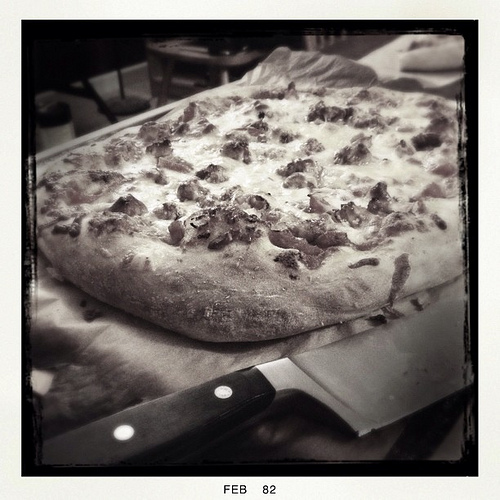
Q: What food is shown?
A: Pizza.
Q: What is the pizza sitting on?
A: A table.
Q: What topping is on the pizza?
A: Hamburger or sausage.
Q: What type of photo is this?
A: Black and white.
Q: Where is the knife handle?
A: Top left of knife.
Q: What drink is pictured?
A: There isn't a drink.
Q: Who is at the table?
A: There are no people.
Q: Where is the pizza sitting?
A: On top of aluminum foil.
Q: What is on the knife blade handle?
A: Two silver dots.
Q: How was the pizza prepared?
A: Baked in oven.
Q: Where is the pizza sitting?
A: On top of cloth napkin.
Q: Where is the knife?
A: Next to the pizza.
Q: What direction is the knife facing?
A: To the right.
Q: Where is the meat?
A: On the pizza.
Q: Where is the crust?
A: On edges of pizza.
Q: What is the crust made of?
A: Bread.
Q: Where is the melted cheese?
A: On the pizza.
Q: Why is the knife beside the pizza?
A: To cut the pizza.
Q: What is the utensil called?
A: A knife.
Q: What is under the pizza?
A: A table.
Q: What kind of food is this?
A: Pizza.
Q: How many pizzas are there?
A: 1.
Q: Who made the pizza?
A: Cook.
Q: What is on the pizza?
A: Meat.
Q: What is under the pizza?
A: Cutting board.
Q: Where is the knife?
A: By the pizza.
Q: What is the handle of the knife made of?
A: Wood.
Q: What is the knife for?
A: Cutting.